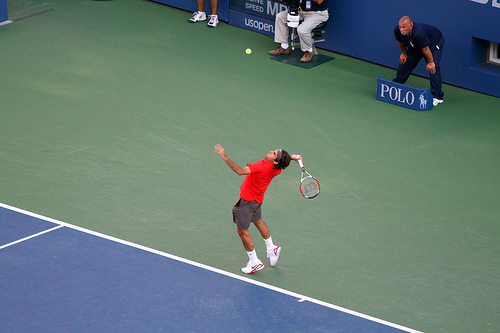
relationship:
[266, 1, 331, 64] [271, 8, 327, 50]
man with pants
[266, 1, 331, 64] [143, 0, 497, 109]
man sitting on sidelines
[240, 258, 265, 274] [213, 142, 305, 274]
shoes worn by man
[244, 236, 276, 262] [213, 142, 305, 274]
socks worn by man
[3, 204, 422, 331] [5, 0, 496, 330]
lines drawn on tennis court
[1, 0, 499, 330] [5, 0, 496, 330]
surface of tennis court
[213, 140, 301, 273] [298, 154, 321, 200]
man holding racket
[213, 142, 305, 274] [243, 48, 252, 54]
man watching ball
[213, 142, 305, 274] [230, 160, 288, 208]
man wearing t-shirt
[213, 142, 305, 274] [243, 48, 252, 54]
man throwing ball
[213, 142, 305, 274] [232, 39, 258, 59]
man hitting ball